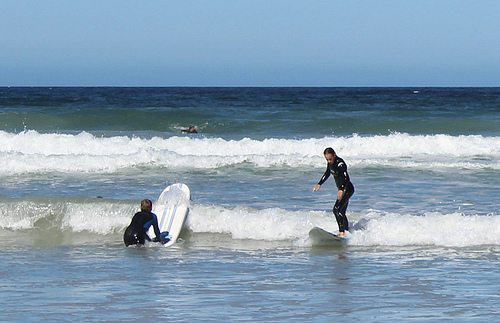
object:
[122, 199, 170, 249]
man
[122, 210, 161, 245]
wet suit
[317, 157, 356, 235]
wet suit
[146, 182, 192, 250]
surfboard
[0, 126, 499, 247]
wave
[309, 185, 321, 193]
hands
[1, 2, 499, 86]
sky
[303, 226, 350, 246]
surfboard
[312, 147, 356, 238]
surfers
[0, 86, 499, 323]
ocean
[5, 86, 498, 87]
horizon line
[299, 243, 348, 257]
reflection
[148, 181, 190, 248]
stripes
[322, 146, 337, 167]
hair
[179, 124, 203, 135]
surfer